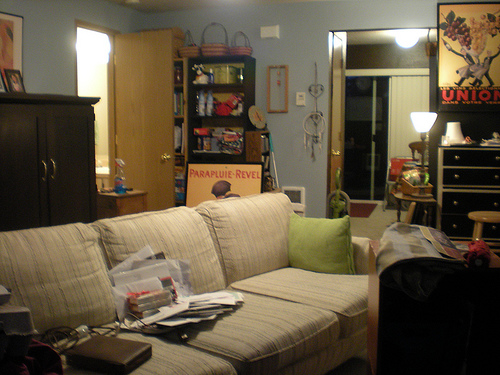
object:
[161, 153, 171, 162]
door knob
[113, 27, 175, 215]
door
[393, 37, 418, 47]
globe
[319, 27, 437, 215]
hallway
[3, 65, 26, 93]
frame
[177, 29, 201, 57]
basket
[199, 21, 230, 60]
basket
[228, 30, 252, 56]
basket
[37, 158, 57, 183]
handles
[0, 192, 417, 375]
sofa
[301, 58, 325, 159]
dream catcher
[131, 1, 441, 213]
wall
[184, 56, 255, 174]
book shelf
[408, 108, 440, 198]
lamp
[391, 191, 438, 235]
table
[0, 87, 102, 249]
doors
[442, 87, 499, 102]
union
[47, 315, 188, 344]
cords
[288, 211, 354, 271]
pillow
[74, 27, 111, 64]
light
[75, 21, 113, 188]
bathroom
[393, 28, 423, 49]
light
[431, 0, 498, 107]
art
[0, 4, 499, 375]
indoors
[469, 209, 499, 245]
chair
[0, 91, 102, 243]
amoire